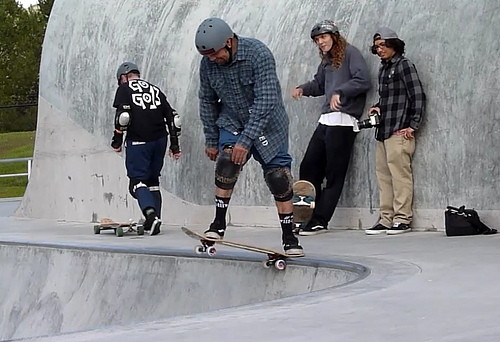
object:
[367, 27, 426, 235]
man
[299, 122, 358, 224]
pants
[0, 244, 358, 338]
ramp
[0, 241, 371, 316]
edge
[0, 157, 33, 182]
fence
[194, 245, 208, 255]
wheels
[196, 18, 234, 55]
helmets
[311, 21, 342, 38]
helmets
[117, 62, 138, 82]
helmets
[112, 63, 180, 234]
person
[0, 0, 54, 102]
tree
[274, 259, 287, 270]
wheel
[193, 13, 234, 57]
gray helmet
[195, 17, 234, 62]
head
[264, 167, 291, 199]
kneepads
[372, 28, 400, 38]
cap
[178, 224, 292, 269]
board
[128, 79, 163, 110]
letter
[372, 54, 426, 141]
shirt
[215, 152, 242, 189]
knee pads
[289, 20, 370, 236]
man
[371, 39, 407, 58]
hair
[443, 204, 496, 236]
bag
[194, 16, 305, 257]
man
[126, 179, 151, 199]
pads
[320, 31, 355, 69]
hair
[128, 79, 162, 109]
words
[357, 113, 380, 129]
camera